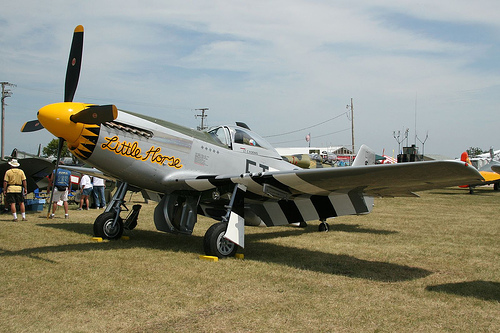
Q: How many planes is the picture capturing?
A: One.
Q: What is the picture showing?
A: A plane.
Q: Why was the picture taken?
A: To capture the airplane.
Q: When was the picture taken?
A: During the day.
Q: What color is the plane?
A: Yellow and gray.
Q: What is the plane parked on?
A: Grass.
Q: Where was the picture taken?
A: At an event.